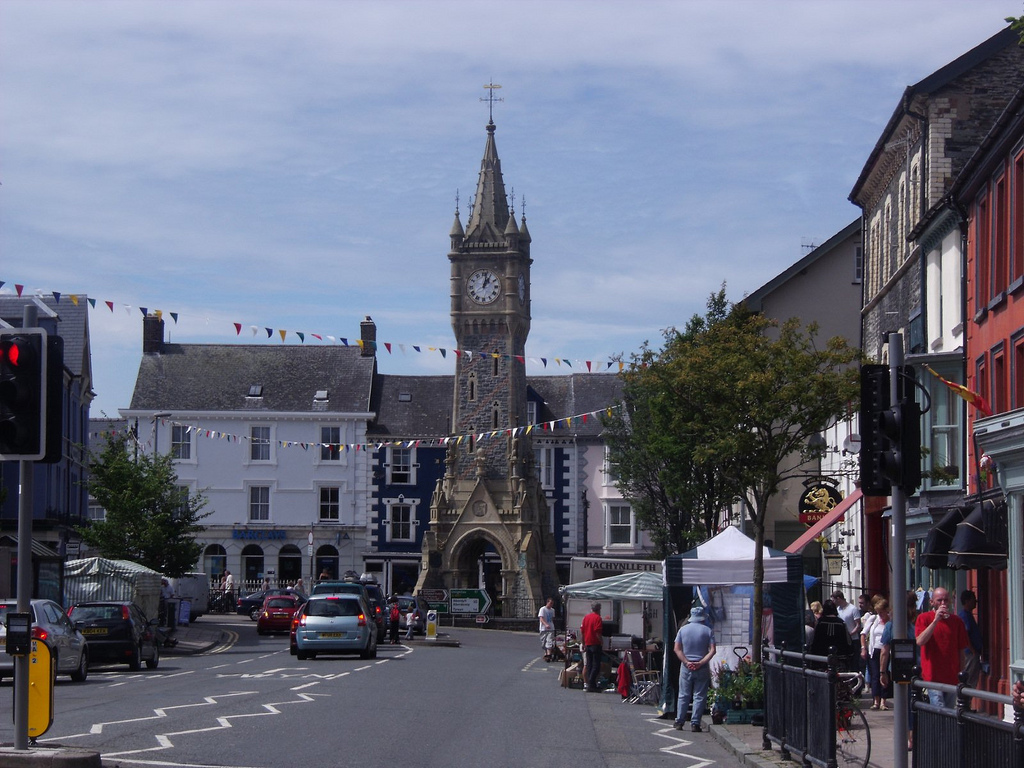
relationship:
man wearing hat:
[674, 603, 719, 739] [680, 600, 720, 628]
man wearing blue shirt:
[674, 603, 719, 739] [672, 622, 719, 668]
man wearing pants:
[674, 603, 719, 739] [671, 659, 718, 729]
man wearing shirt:
[555, 604, 638, 703] [577, 597, 606, 646]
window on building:
[311, 476, 344, 531] [125, 292, 367, 604]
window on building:
[164, 418, 193, 457] [99, 290, 383, 610]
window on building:
[373, 435, 426, 492] [354, 351, 588, 648]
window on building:
[377, 482, 423, 541] [365, 353, 582, 637]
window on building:
[600, 441, 640, 502] [561, 348, 700, 644]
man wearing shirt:
[554, 604, 637, 745] [577, 601, 605, 644]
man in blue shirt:
[675, 601, 717, 738] [677, 625, 716, 667]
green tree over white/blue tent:
[615, 281, 855, 558] [660, 519, 803, 673]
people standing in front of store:
[814, 565, 975, 691] [865, 506, 961, 599]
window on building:
[599, 498, 643, 555] [558, 369, 662, 640]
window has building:
[974, 350, 1014, 428] [840, 8, 1007, 760]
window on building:
[228, 465, 291, 533] [112, 74, 722, 636]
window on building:
[313, 424, 352, 463] [112, 74, 722, 636]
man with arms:
[674, 603, 719, 739] [669, 625, 721, 669]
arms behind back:
[669, 625, 721, 669] [682, 620, 702, 659]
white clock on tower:
[459, 262, 518, 312] [410, 84, 580, 633]